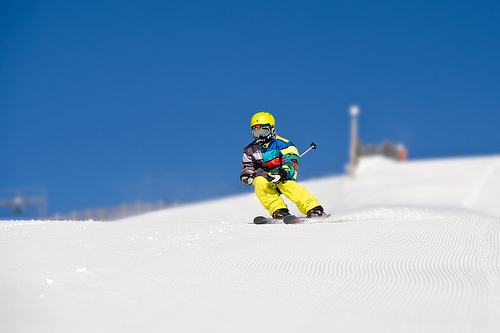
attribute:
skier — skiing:
[203, 88, 364, 247]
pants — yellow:
[252, 180, 314, 221]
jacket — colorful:
[237, 140, 298, 172]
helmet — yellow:
[241, 108, 279, 132]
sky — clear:
[92, 47, 199, 117]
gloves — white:
[227, 167, 287, 190]